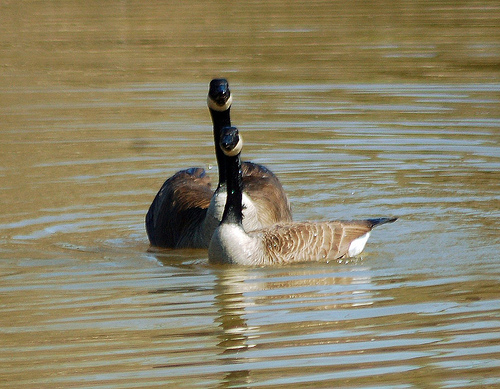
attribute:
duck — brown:
[201, 125, 388, 280]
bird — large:
[144, 78, 295, 247]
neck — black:
[200, 120, 241, 178]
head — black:
[203, 71, 235, 114]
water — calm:
[258, 24, 430, 131]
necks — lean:
[207, 107, 258, 225]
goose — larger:
[142, 68, 294, 249]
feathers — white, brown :
[271, 197, 379, 248]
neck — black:
[224, 153, 243, 228]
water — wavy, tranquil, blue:
[14, 11, 494, 376]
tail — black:
[337, 202, 404, 260]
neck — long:
[202, 141, 263, 231]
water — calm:
[311, 124, 481, 276]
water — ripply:
[300, 108, 462, 262]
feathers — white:
[215, 216, 253, 262]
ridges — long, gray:
[14, 191, 498, 386]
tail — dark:
[364, 208, 402, 232]